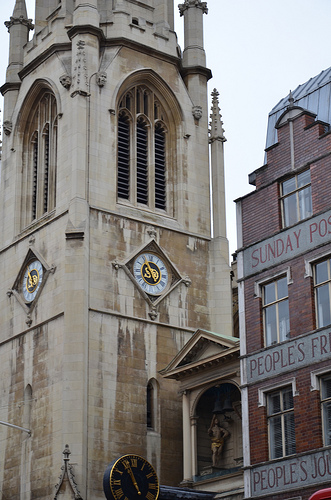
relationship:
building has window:
[236, 59, 329, 498] [274, 162, 319, 236]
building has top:
[236, 59, 329, 498] [236, 82, 329, 234]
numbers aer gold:
[137, 261, 145, 283] [137, 257, 156, 280]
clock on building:
[125, 250, 183, 308] [3, 0, 238, 500]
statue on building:
[201, 418, 235, 469] [236, 59, 329, 498]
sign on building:
[243, 448, 330, 500] [236, 59, 329, 498]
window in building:
[274, 162, 319, 236] [236, 59, 329, 498]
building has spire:
[3, 0, 238, 500] [209, 86, 236, 343]